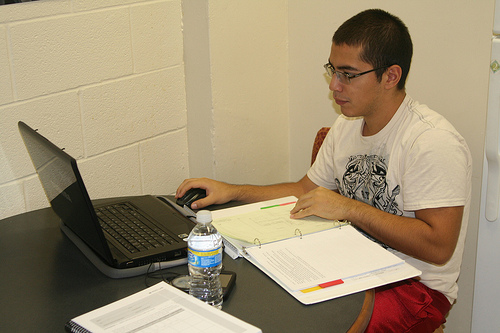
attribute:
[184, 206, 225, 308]
bottle — Plastic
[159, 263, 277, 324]
cell phone — black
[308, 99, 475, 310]
t-shirt — White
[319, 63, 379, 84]
glasses — Pair 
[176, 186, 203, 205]
mouse — black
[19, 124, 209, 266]
laptop — black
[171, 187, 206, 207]
mouse — computer, Electronic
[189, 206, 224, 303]
bottle — water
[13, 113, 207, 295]
laptop — Open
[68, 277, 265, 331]
booklet — binding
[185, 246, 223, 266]
blue label — blue 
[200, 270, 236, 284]
cell phone — black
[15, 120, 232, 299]
computer — Black laptop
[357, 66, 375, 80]
frame — black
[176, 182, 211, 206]
mouse — black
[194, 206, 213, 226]
bottle cap — plastic